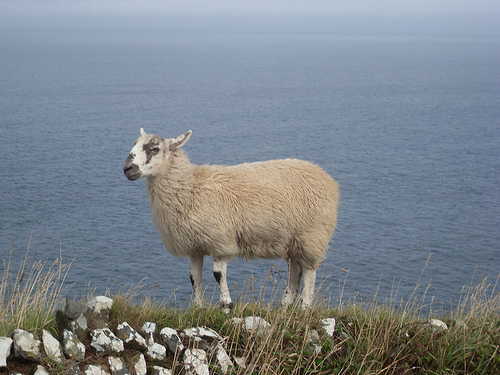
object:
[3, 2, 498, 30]
sky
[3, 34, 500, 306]
water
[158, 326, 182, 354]
rock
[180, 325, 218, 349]
rock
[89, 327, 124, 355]
rock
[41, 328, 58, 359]
rock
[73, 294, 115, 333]
rock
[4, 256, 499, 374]
grass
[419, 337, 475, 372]
weeds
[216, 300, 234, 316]
foot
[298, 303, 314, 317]
foot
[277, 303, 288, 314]
foot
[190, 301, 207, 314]
foot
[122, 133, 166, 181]
face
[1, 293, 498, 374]
hill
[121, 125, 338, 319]
sheep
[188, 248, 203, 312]
front leg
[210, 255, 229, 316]
front leg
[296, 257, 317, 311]
hind leg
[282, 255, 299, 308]
hind leg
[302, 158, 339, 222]
butt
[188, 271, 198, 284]
spot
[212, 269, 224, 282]
spot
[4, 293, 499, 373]
ground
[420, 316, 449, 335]
rock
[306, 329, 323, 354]
rock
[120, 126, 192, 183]
head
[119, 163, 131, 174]
nose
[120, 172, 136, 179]
mouth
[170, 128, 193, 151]
ear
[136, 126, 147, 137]
ear